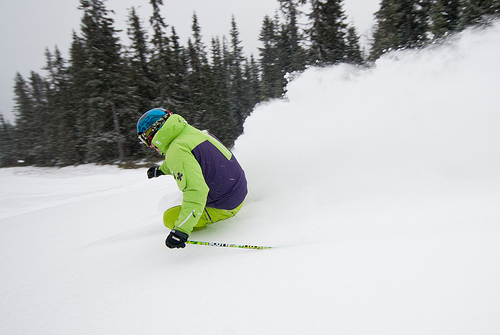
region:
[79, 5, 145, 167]
tall adult evergreen tree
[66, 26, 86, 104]
tall adult evergreen tree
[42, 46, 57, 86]
tall adult evergreen tree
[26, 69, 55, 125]
tall adult evergreen tree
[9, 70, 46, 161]
tall adult evergreen tree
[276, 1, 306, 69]
tall adult evergreen tree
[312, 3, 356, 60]
tall adult evergreen tree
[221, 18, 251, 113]
tall adult evergreen tree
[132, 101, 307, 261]
A skier going down a slope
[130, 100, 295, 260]
A skier going down a slope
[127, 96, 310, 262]
A skier going down a slope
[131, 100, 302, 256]
A skier going down a slope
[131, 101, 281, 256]
A skier going down a slope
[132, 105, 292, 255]
A skier going down a slope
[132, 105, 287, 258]
A skier going down a slope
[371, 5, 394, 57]
tall snow covered tree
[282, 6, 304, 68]
tall snow covered tree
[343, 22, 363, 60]
tall snow covered tree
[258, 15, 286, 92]
tall snow covered tree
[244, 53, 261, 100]
tall snow covered tree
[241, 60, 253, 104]
tall snow covered tree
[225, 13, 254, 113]
tall snow covered tree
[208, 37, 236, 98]
tall snow covered tree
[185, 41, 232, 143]
tall snow covered tree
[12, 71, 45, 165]
tall snow covered tree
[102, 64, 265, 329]
a man is falling down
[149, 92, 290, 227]
man is holding on to the skiing sticks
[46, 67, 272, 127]
the trees are next to the field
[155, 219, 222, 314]
the scarfs rae blck in color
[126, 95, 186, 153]
the helmet is blue in color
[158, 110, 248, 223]
the jacket is blue and black in color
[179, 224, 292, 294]
the skiing sticks are green in color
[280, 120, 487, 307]
the floor is cover of snow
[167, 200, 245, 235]
the pnts are green in color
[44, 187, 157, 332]
the flooor is white in color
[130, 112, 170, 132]
Person wearing helmet on head.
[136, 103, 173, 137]
Person's helmet is blue.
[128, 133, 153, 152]
Person wearing goggles on head.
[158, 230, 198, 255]
Person wearing gloves on hand.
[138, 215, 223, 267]
Person holding ski pole.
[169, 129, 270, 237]
Person wearing green and gray jacket.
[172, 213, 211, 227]
Person wearing green pants.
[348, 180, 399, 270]
Snow on ground is white .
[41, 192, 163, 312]
Ground is covered in snow.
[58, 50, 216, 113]
Large trees in background.